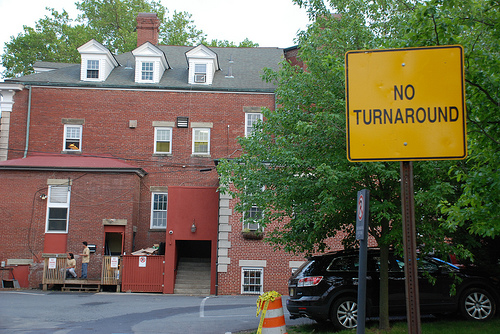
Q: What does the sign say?
A: No turnaround.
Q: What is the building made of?
A: Red bricks.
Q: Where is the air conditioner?
A: Third window on the roof.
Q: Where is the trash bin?
A: Between the platform and the stairs.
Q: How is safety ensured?
A: Signs and safety cones.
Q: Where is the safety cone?
A: Behind the black vehicle.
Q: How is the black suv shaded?
A: Tree.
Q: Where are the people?
A: Small patio.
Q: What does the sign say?
A: No Turnaround.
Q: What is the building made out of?
A: Brick.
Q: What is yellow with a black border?
A: Sign.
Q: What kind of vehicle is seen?
A: SUV.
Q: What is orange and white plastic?
A: Cone.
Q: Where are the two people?
A: In front of the building.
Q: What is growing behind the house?
A: Tree.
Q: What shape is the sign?
A: Square.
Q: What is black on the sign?
A: Lettering.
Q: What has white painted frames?
A: Windows.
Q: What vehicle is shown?
A: Car.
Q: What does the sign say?
A: No turnaround.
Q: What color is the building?
A: Red.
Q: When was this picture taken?
A: Daytime.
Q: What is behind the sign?
A: A tree.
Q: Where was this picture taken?
A: A driveway.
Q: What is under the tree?
A: A car.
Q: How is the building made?
A: Of brick.